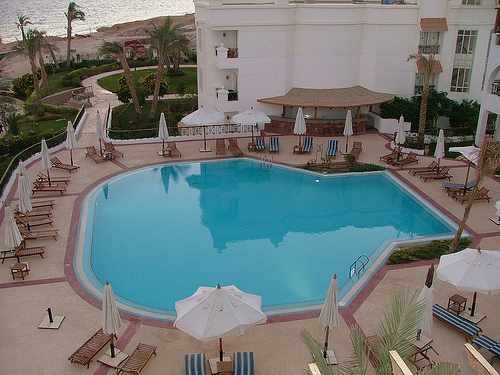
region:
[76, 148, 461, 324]
A large swimming pool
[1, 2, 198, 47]
A body of water in the background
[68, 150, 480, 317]
The pool water is light blue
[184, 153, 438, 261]
Building is casting a shadow over pool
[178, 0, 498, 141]
A building in the background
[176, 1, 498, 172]
Building is white in color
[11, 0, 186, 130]
Palm trees in the background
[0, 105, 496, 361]
Beach umbrellas are surrounding the pool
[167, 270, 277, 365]
Beach umbrella is white in color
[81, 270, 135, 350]
Beach umbrella is closed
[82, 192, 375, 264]
Blue water in large swimming pool.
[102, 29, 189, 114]
Green and palm trees on the left side.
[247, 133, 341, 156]
Row of blue and white chaise chairs.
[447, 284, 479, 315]
Brown small four legged side table.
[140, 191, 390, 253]
Building reflection is in the pool.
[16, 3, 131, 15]
Water with waves showing in it.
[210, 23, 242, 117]
Two balconies on side of building.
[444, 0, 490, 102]
Three sets of windows on right side of building.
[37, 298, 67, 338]
Empty black and white umbrella holder.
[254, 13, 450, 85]
White painted building with brown awnings.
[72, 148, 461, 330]
blue hotel swimming pool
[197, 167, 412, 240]
reflection of building in pool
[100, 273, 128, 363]
folded up beach umbrella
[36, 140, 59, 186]
folded up beach umbrella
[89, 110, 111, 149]
folded up beach umbrella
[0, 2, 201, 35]
partial view of body of water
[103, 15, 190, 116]
palm tress next to bullding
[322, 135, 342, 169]
blue and white striped chair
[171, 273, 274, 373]
white open umbrella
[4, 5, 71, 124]
palm trees by the beach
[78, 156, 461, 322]
A large clear blue swimming pool.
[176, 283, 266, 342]
A white beach umbrella.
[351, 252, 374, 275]
A silver pool ladder.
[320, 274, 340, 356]
A white closed umbrella on a wooden pole.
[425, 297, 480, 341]
A blue and white striped pool lounging chair.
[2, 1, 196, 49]
The ocean.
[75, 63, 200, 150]
A grey walking path.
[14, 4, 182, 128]
Palm trees.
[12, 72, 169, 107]
Small green and yellow bushes.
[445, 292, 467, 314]
A small wooden table.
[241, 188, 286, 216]
reflection in the water.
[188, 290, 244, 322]
umbrella on a pole.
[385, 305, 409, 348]
leaves on the tree.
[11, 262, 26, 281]
table near the umbrella.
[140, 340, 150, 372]
chair near the pool.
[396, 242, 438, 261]
bushes near the pool.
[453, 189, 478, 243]
trunk of the tree.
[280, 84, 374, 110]
canopy over the bar.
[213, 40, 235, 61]
balcony on the building.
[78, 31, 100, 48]
sand on the beach.